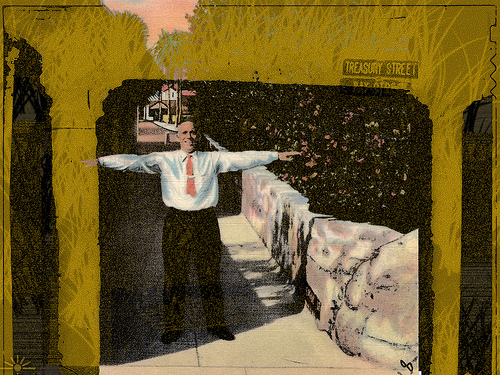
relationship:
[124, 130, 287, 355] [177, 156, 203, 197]
man in tie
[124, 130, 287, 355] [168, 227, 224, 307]
man with pants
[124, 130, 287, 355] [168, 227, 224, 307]
man in pants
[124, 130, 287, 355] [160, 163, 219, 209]
man in shirt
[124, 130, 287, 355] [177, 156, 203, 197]
man with tie